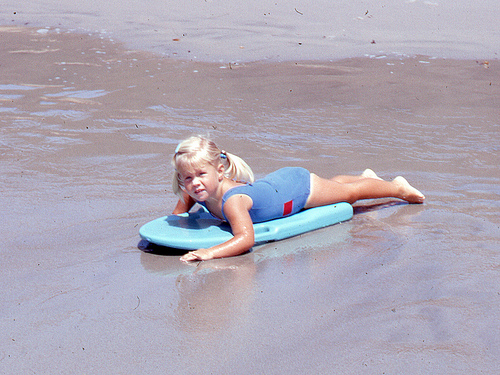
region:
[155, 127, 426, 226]
this is a baby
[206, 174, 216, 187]
the baby has a light skin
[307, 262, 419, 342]
this is a water body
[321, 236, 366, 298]
the water is calm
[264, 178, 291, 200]
this is a swimming costume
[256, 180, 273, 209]
the swimming costume is blue in color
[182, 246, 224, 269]
the girl is touching water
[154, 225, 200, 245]
this is a board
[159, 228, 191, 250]
the board is blue in color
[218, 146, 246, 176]
her hair is long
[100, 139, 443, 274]
a girl laying on a boogie board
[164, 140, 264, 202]
the girl has blonde hair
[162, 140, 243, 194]
the girl's hair is in ponytails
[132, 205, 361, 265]
the boogie board is light blue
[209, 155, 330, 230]
the girl's bathing suit is blue with a red stripe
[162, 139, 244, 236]
the girl is looking at the camera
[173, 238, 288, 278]
the girl has her arm on the sand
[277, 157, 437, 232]
the girl's legs hang off the back of the board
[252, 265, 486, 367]
wet sand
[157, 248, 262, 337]
reflection of the girl in the sand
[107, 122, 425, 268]
a little girl lying on floatie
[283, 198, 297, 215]
a red stripe on a bathing suit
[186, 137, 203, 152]
blonde hair on a hair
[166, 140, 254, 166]
hair styled in two pigtails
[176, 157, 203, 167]
blond bangs covering a forehead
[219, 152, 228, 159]
a blue barrette in hair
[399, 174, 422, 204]
a bare foot resting in the water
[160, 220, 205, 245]
a plastic blue floatie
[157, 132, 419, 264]
a little girl wearing a blue bathing suit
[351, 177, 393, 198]
tan skin on a little leg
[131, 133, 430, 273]
girl on blue surfboard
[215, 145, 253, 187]
ponytail in blonde hair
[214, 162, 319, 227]
blue one piece bathing suit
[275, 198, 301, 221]
red box on bathing suit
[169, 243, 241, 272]
arm on wet sand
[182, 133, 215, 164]
blonde hair parted to the side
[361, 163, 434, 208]
feet in wet sand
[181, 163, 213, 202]
girl's face looking up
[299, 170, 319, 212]
white line on top of leg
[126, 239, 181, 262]
shadow under surf board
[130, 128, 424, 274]
The person is on a boogie board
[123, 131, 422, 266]
the girl is wearing a one piece suit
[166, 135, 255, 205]
the girl has blonde pigtails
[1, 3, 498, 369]
The sand is wet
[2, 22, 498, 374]
the water has come in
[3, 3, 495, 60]
the sand is tan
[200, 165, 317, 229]
the bathing suit is blue with a red stripe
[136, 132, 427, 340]
the water is reflecting the little girl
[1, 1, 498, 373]
the scene is outdoors